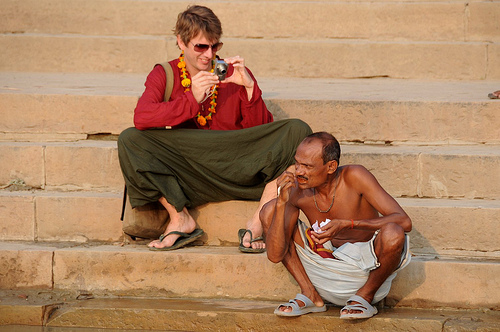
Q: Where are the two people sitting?
A: Stairs.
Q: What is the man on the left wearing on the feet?
A: Flip flops.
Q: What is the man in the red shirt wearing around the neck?
A: Yellow necklace.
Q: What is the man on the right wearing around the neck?
A: Metal chain.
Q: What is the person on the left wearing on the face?
A: Sunglasses.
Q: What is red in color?
A: Shirt.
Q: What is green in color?
A: Pants.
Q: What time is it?
A: Afternoon.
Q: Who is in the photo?
A: Two people.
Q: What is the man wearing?
A: Sunglasses.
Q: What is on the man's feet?
A: Sandals.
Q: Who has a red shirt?
A: The man.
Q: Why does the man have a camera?
A: He is taking a photo.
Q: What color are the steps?
A: Tan.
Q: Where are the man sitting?
A: On the steps.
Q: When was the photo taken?
A: Daytime.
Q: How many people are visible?
A: Two.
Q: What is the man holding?
A: A camera.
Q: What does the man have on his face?
A: Sunglasses.